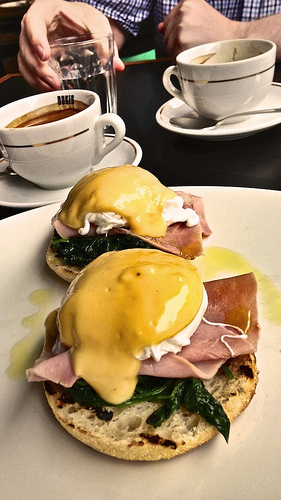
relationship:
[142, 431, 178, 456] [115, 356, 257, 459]
part of bun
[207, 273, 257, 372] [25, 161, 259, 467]
meat on burger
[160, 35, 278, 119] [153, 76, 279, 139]
teacup on plate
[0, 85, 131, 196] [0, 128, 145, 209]
teacup on plate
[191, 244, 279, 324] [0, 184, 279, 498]
sauce on plate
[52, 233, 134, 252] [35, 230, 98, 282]
leaf on english muffin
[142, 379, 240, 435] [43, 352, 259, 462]
leaf on bun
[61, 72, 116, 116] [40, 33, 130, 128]
liquid in glass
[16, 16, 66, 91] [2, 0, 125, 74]
fingers on hand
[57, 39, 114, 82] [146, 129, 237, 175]
glass on table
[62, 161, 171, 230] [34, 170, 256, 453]
cheese on burger